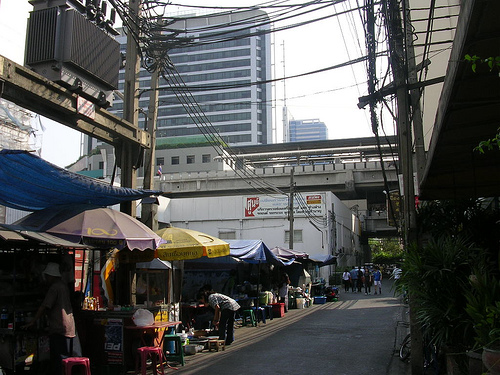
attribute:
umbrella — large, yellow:
[149, 224, 229, 259]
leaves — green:
[399, 223, 500, 357]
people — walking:
[342, 265, 385, 297]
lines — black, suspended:
[106, 1, 402, 71]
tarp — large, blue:
[201, 237, 278, 263]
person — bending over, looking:
[203, 290, 238, 343]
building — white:
[106, 180, 366, 293]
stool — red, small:
[139, 347, 167, 372]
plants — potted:
[406, 186, 500, 372]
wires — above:
[129, 1, 441, 96]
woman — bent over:
[203, 291, 242, 342]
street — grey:
[157, 252, 411, 370]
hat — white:
[42, 262, 65, 276]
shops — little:
[7, 151, 329, 371]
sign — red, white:
[246, 190, 326, 221]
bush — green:
[390, 140, 497, 373]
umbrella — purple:
[9, 197, 165, 252]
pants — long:
[344, 279, 374, 295]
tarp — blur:
[306, 253, 335, 265]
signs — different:
[80, 316, 137, 369]